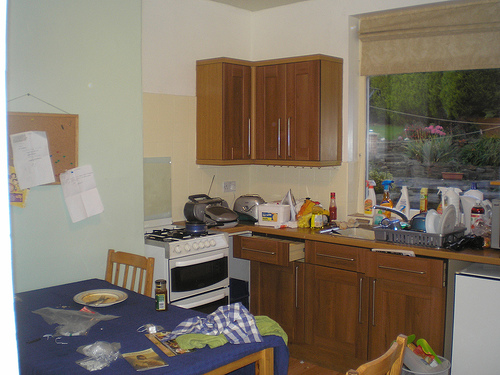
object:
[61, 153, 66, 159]
push pins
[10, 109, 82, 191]
cork boad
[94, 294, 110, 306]
2 utensils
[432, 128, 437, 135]
flowers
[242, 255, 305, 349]
cupboard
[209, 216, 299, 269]
cupboard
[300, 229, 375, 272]
cupboard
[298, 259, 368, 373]
cupboard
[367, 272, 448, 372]
cupboard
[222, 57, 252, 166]
cupboard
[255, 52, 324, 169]
cupboard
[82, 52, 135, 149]
walls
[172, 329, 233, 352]
cloths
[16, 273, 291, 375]
table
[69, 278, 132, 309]
dishes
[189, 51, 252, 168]
cabinet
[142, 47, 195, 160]
wall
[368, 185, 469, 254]
drain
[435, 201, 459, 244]
dishes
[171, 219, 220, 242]
pan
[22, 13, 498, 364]
kitchen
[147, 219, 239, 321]
stove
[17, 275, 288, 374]
dining table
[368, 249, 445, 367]
kitchen cabinets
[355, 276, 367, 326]
pulls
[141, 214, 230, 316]
stove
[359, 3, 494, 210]
window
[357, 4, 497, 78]
shade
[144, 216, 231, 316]
range